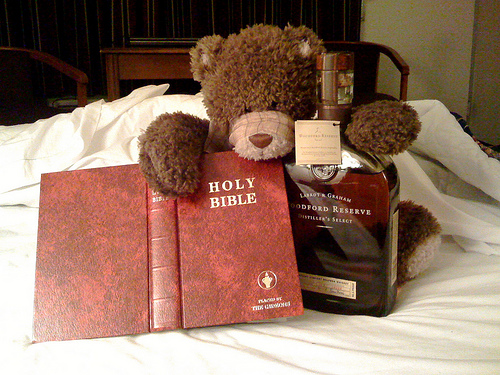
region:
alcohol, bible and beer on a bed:
[3, 15, 479, 366]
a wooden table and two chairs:
[6, 35, 412, 107]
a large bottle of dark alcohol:
[281, 42, 401, 317]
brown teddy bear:
[138, 22, 439, 278]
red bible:
[38, 176, 306, 336]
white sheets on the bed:
[1, 107, 489, 367]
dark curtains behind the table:
[0, 0, 350, 105]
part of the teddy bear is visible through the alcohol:
[296, 205, 437, 313]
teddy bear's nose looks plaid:
[223, 110, 288, 141]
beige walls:
[359, 0, 494, 145]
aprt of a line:
[173, 265, 196, 311]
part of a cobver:
[180, 226, 243, 304]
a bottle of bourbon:
[276, 35, 453, 346]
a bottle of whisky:
[276, 47, 421, 324]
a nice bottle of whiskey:
[268, 30, 443, 321]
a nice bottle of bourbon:
[281, 39, 422, 321]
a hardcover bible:
[21, 140, 348, 352]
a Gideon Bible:
[20, 122, 334, 356]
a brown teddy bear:
[142, 26, 478, 326]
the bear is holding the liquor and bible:
[86, 2, 483, 370]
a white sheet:
[1, 81, 498, 366]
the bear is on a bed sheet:
[19, 0, 451, 373]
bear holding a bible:
[45, 150, 297, 359]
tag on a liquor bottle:
[289, 116, 353, 169]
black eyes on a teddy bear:
[238, 100, 285, 115]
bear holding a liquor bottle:
[276, 74, 429, 305]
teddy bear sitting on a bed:
[107, 14, 476, 313]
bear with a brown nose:
[248, 125, 275, 160]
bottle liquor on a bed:
[283, 138, 388, 303]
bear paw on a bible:
[136, 123, 188, 203]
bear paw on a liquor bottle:
[306, 51, 407, 164]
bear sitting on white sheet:
[142, 58, 386, 294]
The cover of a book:
[66, 206, 121, 244]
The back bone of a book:
[156, 232, 168, 287]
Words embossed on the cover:
[214, 198, 240, 204]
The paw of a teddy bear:
[153, 156, 193, 186]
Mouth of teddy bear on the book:
[246, 150, 274, 157]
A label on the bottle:
[305, 132, 329, 159]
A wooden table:
[136, 64, 185, 73]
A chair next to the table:
[361, 62, 372, 91]